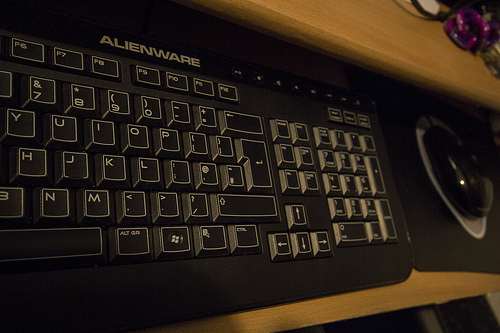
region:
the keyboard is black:
[17, 57, 416, 253]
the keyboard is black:
[66, 56, 423, 273]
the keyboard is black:
[35, 57, 367, 277]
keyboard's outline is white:
[29, 63, 418, 302]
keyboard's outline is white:
[20, 72, 382, 266]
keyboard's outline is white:
[12, 76, 369, 271]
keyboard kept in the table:
[13, 90, 367, 260]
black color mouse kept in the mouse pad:
[406, 115, 498, 247]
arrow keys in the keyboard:
[278, 200, 327, 270]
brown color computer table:
[332, 3, 495, 85]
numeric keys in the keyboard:
[323, 125, 391, 242]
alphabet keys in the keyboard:
[23, 111, 114, 217]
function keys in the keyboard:
[19, 34, 234, 92]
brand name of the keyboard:
[94, 23, 217, 69]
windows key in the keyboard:
[162, 228, 185, 250]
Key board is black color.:
[45, 36, 410, 314]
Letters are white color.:
[23, 53, 370, 263]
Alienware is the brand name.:
[96, 30, 209, 70]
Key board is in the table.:
[197, 188, 385, 319]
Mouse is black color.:
[412, 110, 494, 225]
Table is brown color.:
[271, 1, 482, 113]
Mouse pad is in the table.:
[427, 220, 492, 330]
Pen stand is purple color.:
[437, 1, 492, 71]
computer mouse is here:
[413, 119, 490, 231]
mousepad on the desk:
[413, 248, 492, 280]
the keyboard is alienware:
[82, 33, 215, 80]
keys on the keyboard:
[115, 173, 253, 253]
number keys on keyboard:
[312, 141, 392, 243]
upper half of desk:
[317, 18, 490, 96]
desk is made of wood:
[327, 29, 454, 91]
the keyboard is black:
[222, 275, 370, 288]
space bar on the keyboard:
[13, 221, 106, 269]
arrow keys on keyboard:
[276, 210, 331, 265]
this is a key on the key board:
[266, 227, 298, 267]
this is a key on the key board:
[264, 165, 299, 192]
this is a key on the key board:
[146, 193, 182, 217]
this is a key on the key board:
[81, 180, 115, 216]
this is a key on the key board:
[134, 153, 166, 186]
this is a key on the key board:
[181, 135, 206, 167]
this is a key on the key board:
[106, 86, 140, 119]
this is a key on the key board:
[220, 105, 273, 137]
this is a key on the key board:
[97, 81, 137, 121]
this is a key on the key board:
[61, 142, 108, 187]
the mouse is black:
[423, 123, 492, 217]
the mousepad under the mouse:
[380, 99, 499, 275]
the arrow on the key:
[310, 231, 331, 258]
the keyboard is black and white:
[3, 6, 412, 331]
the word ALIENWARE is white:
[100, 33, 202, 66]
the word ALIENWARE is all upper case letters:
[98, 34, 200, 67]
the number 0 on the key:
[135, 93, 162, 126]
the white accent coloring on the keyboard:
[2, 10, 413, 332]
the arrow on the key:
[211, 192, 279, 225]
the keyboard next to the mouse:
[1, 2, 496, 329]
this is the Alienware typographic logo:
[88, 24, 227, 76]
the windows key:
[160, 223, 187, 255]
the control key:
[230, 219, 270, 266]